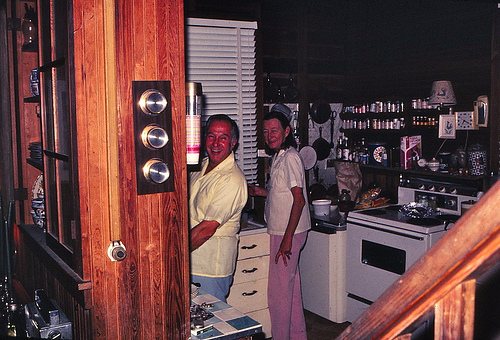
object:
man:
[188, 115, 249, 304]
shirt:
[191, 151, 247, 278]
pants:
[267, 229, 310, 338]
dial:
[141, 160, 172, 186]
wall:
[74, 1, 190, 338]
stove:
[346, 205, 458, 323]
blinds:
[188, 17, 259, 212]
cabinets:
[224, 228, 273, 339]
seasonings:
[341, 99, 407, 136]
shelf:
[338, 111, 409, 119]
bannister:
[339, 181, 499, 336]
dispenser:
[186, 80, 205, 170]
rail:
[332, 180, 498, 339]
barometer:
[131, 81, 176, 196]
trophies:
[0, 277, 20, 338]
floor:
[1, 275, 53, 339]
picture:
[439, 114, 457, 139]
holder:
[184, 79, 203, 118]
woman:
[249, 113, 313, 339]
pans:
[311, 101, 332, 124]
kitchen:
[184, 1, 498, 338]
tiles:
[189, 284, 264, 339]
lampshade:
[429, 79, 459, 106]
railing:
[335, 176, 498, 339]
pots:
[264, 76, 302, 104]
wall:
[188, 3, 370, 205]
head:
[203, 113, 240, 161]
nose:
[213, 138, 220, 146]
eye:
[208, 133, 213, 139]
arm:
[184, 180, 239, 249]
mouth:
[210, 148, 223, 154]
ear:
[231, 139, 237, 149]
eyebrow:
[220, 134, 230, 138]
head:
[262, 112, 292, 151]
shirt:
[265, 147, 316, 235]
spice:
[375, 101, 382, 112]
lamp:
[427, 80, 456, 115]